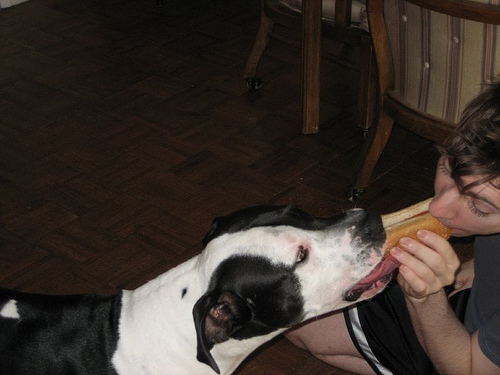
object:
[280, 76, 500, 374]
man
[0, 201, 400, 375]
dog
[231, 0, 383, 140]
chair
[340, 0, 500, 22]
table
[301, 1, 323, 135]
leg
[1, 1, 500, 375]
floor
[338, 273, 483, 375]
shorts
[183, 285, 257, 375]
ear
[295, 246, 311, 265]
eye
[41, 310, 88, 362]
fur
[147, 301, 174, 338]
white fur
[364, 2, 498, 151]
back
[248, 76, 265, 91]
coaster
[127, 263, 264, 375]
neck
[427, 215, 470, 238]
mouth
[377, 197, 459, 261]
bun